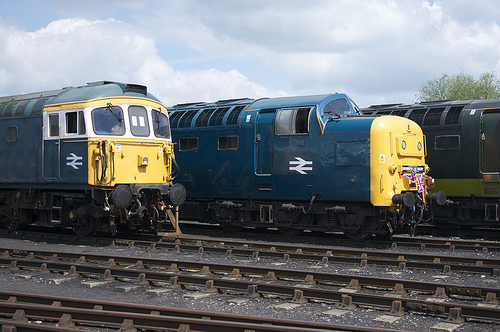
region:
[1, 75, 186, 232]
A blue and yellow train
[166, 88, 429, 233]
Another blue and yellow train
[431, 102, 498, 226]
The side of a train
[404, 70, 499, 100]
The top of a tree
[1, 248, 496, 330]
Railroad tracks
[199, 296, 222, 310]
Gravel on the ground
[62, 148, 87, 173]
A logo on the train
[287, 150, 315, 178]
A logo on the other train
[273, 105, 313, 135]
A window on the train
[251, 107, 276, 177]
A door on the train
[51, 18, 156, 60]
cloud in the sky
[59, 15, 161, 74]
white cloud above the ground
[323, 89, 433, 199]
blue and yellow train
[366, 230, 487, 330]
tracks on the ground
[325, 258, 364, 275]
rocks next to the track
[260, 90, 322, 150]
window on the side of the train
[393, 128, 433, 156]
lights on the front of the train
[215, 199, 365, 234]
bottom part of the train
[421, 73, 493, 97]
leaves in the background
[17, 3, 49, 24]
blue sky above the land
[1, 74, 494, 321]
trains at a railway station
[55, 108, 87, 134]
the window is open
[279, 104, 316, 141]
one of the windows is open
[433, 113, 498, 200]
a dark green train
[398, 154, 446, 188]
a flag in the front of the train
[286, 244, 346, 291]
brown shiny rail lines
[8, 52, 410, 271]
the trains are blue with a yellow front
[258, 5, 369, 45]
the sky is cloudy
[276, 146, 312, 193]
logo on the train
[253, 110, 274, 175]
the door is shut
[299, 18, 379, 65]
white clouds in the sky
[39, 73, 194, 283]
front of the train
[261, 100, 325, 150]
side window on the train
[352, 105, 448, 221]
yellow part of the train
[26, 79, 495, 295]
three different trains in the photo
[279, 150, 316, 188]
white logo on the train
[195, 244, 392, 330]
many tracks on the ground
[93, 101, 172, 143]
windows on the front of the train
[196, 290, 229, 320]
rocks next to the train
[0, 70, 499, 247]
THREE TRAINS NEXT TO EACH OTHER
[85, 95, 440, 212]
THE FRONT OF THE ENGINES ARE YELLOW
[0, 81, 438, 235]
THE TRAINS ARE BLUE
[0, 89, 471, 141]
THE TRAINS HAVE MANY WINDOWS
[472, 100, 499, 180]
THIS IS THE DOOR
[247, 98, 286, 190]
THE DOOR IS ON THE TRAIN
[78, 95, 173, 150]
THE WINDSHIELD IS ON THE ENGINE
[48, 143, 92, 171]
THE LOGO IS ON THE SIDE OF THE TRAIN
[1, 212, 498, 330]
THERE ARE MANY TRACKS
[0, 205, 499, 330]
THE TRACKS ARE SIDE BY SIDE